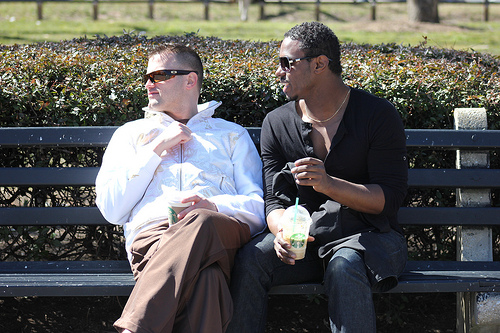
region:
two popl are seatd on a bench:
[124, 59, 384, 329]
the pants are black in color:
[321, 235, 388, 332]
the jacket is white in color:
[143, 108, 245, 219]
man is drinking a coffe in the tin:
[224, 44, 381, 280]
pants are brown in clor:
[149, 228, 229, 332]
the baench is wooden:
[13, 152, 89, 299]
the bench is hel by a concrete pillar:
[456, 162, 492, 299]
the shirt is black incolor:
[290, 143, 397, 237]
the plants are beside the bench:
[395, 42, 482, 99]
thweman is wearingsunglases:
[255, 23, 363, 168]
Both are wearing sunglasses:
[96, 10, 391, 331]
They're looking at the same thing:
[124, 15, 359, 125]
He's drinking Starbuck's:
[252, 10, 397, 320]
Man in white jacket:
[86, 32, 267, 329]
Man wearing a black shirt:
[252, 10, 407, 325]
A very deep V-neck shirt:
[278, 90, 363, 178]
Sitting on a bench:
[13, 17, 498, 328]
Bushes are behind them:
[27, 13, 483, 301]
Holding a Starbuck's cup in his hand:
[155, 183, 221, 234]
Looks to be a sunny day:
[29, 15, 483, 330]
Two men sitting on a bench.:
[95, 20, 408, 331]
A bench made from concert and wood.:
[0, 108, 499, 331]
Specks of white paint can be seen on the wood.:
[2, 125, 498, 297]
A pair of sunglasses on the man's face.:
[141, 68, 200, 83]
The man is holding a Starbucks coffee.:
[232, 21, 407, 331]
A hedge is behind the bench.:
[0, 30, 499, 330]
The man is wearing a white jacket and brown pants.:
[95, 43, 265, 329]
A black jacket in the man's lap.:
[272, 161, 397, 292]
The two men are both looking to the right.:
[95, 22, 405, 330]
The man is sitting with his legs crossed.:
[95, 44, 263, 331]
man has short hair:
[142, 41, 228, 69]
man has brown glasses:
[146, 59, 218, 97]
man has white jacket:
[111, 122, 270, 217]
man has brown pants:
[82, 209, 258, 315]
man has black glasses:
[271, 51, 330, 75]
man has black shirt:
[266, 112, 409, 252]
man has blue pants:
[250, 209, 422, 326]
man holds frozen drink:
[265, 185, 321, 295]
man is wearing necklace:
[302, 82, 357, 124]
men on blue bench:
[27, 113, 499, 325]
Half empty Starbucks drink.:
[277, 194, 313, 261]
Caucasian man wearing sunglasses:
[92, 44, 269, 328]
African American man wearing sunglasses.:
[227, 21, 414, 328]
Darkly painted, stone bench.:
[2, 120, 494, 295]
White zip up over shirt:
[93, 107, 265, 237]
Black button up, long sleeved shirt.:
[245, 87, 406, 239]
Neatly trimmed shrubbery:
[6, 34, 486, 259]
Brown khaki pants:
[114, 208, 261, 326]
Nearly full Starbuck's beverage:
[164, 190, 196, 227]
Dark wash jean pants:
[231, 221, 382, 330]